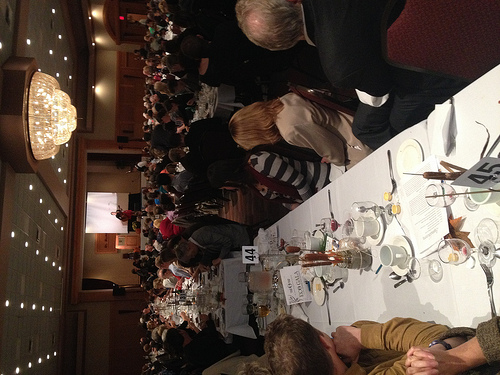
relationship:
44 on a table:
[241, 243, 258, 267] [217, 65, 499, 373]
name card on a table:
[278, 262, 312, 305] [217, 65, 499, 373]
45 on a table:
[451, 157, 500, 194] [217, 65, 499, 373]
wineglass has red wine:
[316, 214, 358, 236] [333, 221, 341, 230]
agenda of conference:
[395, 166, 450, 257] [72, 9, 496, 374]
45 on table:
[451, 157, 500, 194] [217, 65, 499, 373]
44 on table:
[241, 243, 258, 267] [217, 65, 499, 373]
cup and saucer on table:
[378, 237, 415, 279] [217, 65, 499, 373]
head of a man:
[261, 311, 351, 374] [270, 315, 448, 374]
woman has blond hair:
[229, 89, 371, 167] [225, 99, 285, 151]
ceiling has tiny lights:
[3, 5, 84, 257] [39, 0, 78, 92]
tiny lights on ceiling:
[39, 0, 78, 92] [3, 5, 84, 257]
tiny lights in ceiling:
[39, 0, 78, 92] [3, 5, 84, 257]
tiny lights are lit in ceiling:
[39, 0, 78, 92] [3, 5, 84, 257]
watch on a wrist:
[426, 337, 454, 352] [424, 333, 461, 357]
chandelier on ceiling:
[26, 71, 82, 157] [3, 5, 84, 257]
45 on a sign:
[451, 157, 500, 194] [450, 154, 498, 194]